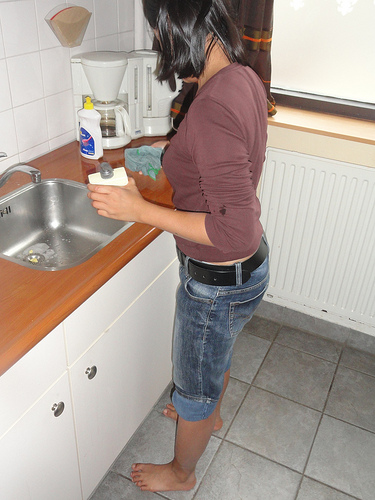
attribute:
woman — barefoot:
[87, 0, 272, 492]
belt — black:
[173, 231, 269, 286]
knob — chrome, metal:
[85, 364, 99, 382]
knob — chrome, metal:
[50, 400, 66, 418]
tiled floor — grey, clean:
[85, 315, 374, 498]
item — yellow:
[25, 248, 39, 264]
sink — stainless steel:
[0, 174, 135, 274]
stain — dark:
[218, 203, 230, 218]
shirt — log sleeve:
[159, 64, 269, 262]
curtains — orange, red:
[219, 0, 279, 120]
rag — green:
[124, 144, 164, 182]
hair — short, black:
[141, 1, 250, 82]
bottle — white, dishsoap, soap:
[75, 95, 104, 160]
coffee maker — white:
[69, 49, 131, 150]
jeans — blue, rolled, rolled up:
[169, 242, 270, 421]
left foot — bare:
[131, 458, 198, 494]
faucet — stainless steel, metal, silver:
[1, 147, 43, 190]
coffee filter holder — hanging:
[44, 1, 94, 49]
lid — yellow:
[81, 94, 96, 112]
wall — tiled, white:
[0, 1, 134, 179]